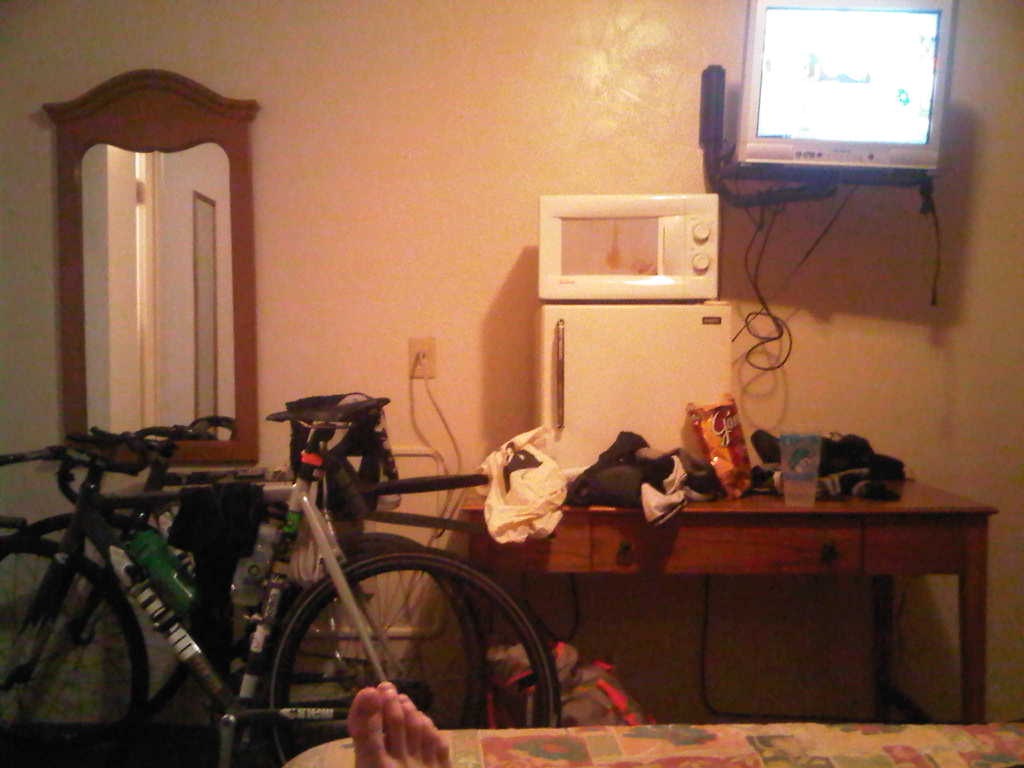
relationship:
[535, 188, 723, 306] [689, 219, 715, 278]
microwave has dials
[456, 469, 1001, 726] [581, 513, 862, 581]
table has drawer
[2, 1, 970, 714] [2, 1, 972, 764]
wall on side of building